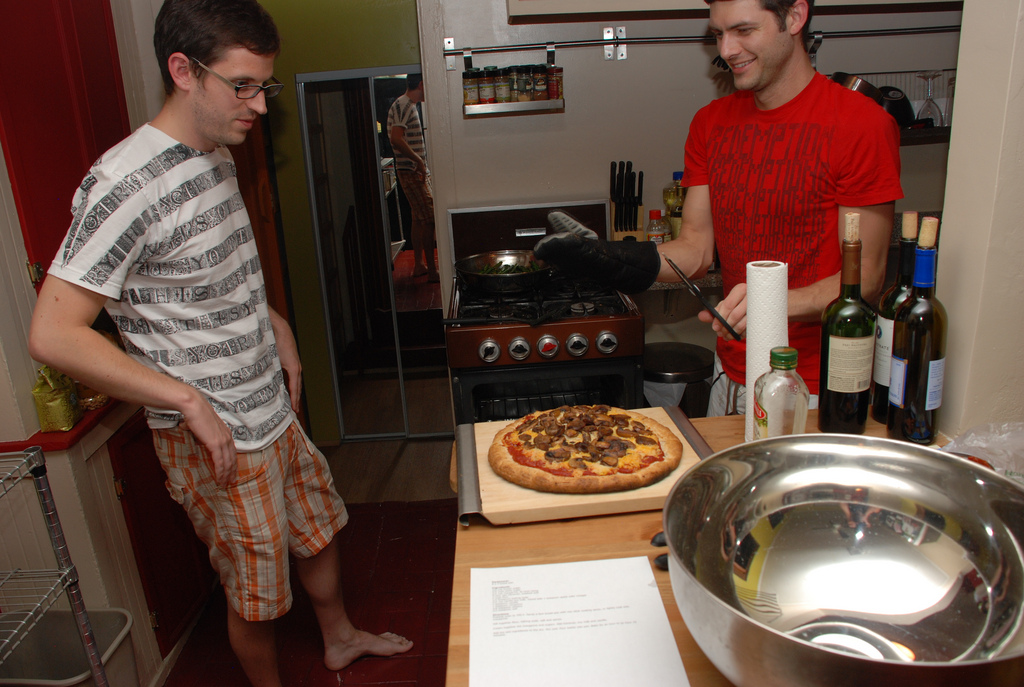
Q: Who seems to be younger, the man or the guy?
A: The man is younger than the guy.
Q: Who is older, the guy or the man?
A: The guy is older than the man.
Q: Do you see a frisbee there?
A: No, there are no frisbees.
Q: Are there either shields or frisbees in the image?
A: No, there are no frisbees or shields.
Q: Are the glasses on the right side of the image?
A: No, the glasses are on the left of the image.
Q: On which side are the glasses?
A: The glasses are on the left of the image.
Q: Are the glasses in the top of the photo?
A: Yes, the glasses are in the top of the image.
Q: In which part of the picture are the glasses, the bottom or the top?
A: The glasses are in the top of the image.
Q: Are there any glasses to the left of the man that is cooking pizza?
A: Yes, there are glasses to the left of the man.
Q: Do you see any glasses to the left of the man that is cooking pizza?
A: Yes, there are glasses to the left of the man.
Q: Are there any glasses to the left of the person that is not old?
A: Yes, there are glasses to the left of the man.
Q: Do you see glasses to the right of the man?
A: No, the glasses are to the left of the man.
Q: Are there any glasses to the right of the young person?
A: No, the glasses are to the left of the man.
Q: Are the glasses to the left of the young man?
A: Yes, the glasses are to the left of the man.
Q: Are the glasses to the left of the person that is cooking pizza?
A: Yes, the glasses are to the left of the man.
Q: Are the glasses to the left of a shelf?
A: No, the glasses are to the left of the man.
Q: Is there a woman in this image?
A: No, there are no women.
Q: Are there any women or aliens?
A: No, there are no women or aliens.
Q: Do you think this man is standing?
A: Yes, the man is standing.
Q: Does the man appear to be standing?
A: Yes, the man is standing.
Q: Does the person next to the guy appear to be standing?
A: Yes, the man is standing.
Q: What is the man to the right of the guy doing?
A: The man is standing.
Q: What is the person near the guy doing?
A: The man is standing.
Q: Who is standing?
A: The man is standing.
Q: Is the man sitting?
A: No, the man is standing.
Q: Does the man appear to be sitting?
A: No, the man is standing.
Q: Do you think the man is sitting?
A: No, the man is standing.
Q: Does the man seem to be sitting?
A: No, the man is standing.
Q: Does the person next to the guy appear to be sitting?
A: No, the man is standing.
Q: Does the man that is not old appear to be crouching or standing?
A: The man is standing.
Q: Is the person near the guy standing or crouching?
A: The man is standing.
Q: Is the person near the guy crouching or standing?
A: The man is standing.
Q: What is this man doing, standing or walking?
A: The man is standing.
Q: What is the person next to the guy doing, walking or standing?
A: The man is standing.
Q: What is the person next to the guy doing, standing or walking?
A: The man is standing.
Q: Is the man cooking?
A: Yes, the man is cooking.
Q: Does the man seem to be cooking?
A: Yes, the man is cooking.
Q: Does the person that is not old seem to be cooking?
A: Yes, the man is cooking.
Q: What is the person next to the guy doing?
A: The man is cooking.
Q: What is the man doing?
A: The man is cooking.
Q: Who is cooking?
A: The man is cooking.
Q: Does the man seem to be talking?
A: No, the man is cooking.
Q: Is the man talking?
A: No, the man is cooking.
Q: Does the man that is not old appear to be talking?
A: No, the man is cooking.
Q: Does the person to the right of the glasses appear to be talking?
A: No, the man is cooking.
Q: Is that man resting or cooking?
A: The man is cooking.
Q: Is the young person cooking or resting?
A: The man is cooking.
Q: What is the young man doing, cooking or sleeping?
A: The man is cooking.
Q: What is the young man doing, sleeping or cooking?
A: The man is cooking.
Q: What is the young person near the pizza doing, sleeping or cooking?
A: The man is cooking.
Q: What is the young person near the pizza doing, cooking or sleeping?
A: The man is cooking.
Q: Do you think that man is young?
A: Yes, the man is young.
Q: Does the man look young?
A: Yes, the man is young.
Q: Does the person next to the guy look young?
A: Yes, the man is young.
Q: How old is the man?
A: The man is young.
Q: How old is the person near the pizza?
A: The man is young.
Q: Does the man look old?
A: No, the man is young.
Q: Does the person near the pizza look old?
A: No, the man is young.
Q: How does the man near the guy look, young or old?
A: The man is young.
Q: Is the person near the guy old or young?
A: The man is young.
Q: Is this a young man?
A: Yes, this is a young man.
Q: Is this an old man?
A: No, this is a young man.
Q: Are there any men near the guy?
A: Yes, there is a man near the guy.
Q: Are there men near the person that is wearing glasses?
A: Yes, there is a man near the guy.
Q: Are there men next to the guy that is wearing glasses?
A: Yes, there is a man next to the guy.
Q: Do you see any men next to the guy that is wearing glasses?
A: Yes, there is a man next to the guy.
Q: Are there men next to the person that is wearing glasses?
A: Yes, there is a man next to the guy.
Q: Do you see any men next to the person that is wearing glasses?
A: Yes, there is a man next to the guy.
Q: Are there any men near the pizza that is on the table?
A: Yes, there is a man near the pizza.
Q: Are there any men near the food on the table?
A: Yes, there is a man near the pizza.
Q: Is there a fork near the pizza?
A: No, there is a man near the pizza.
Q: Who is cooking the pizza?
A: The man is cooking the pizza.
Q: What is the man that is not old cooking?
A: The man is cooking pizza.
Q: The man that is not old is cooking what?
A: The man is cooking pizza.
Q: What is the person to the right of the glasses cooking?
A: The man is cooking pizza.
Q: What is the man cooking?
A: The man is cooking pizza.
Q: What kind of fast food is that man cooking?
A: The man is cooking pizza.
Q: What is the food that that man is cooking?
A: The food is a pizza.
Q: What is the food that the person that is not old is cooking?
A: The food is a pizza.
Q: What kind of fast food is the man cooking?
A: The man is cooking pizza.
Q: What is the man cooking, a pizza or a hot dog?
A: The man is cooking a pizza.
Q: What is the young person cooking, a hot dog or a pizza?
A: The man is cooking a pizza.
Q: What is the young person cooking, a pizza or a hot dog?
A: The man is cooking a pizza.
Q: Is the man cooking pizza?
A: Yes, the man is cooking pizza.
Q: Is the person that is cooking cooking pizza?
A: Yes, the man is cooking pizza.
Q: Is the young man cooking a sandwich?
A: No, the man is cooking pizza.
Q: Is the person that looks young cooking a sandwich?
A: No, the man is cooking pizza.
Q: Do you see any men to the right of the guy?
A: Yes, there is a man to the right of the guy.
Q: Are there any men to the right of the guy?
A: Yes, there is a man to the right of the guy.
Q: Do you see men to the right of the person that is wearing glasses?
A: Yes, there is a man to the right of the guy.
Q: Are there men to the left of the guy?
A: No, the man is to the right of the guy.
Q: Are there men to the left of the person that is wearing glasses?
A: No, the man is to the right of the guy.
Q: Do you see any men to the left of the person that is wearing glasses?
A: No, the man is to the right of the guy.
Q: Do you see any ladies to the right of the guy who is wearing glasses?
A: No, there is a man to the right of the guy.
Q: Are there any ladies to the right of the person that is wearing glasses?
A: No, there is a man to the right of the guy.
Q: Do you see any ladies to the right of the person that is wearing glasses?
A: No, there is a man to the right of the guy.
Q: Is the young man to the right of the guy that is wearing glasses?
A: Yes, the man is to the right of the guy.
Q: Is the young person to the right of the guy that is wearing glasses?
A: Yes, the man is to the right of the guy.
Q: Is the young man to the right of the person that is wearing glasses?
A: Yes, the man is to the right of the guy.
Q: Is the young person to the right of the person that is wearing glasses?
A: Yes, the man is to the right of the guy.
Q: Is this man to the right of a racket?
A: No, the man is to the right of the guy.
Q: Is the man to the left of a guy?
A: No, the man is to the right of a guy.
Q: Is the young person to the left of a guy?
A: No, the man is to the right of a guy.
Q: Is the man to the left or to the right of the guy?
A: The man is to the right of the guy.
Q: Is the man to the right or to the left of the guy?
A: The man is to the right of the guy.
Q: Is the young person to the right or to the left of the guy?
A: The man is to the right of the guy.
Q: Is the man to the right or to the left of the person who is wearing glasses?
A: The man is to the right of the guy.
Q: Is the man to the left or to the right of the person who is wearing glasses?
A: The man is to the right of the guy.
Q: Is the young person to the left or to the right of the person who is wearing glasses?
A: The man is to the right of the guy.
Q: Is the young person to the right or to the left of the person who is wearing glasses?
A: The man is to the right of the guy.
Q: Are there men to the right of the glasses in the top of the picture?
A: Yes, there is a man to the right of the glasses.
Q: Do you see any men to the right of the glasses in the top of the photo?
A: Yes, there is a man to the right of the glasses.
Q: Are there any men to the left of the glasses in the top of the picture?
A: No, the man is to the right of the glasses.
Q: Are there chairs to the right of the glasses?
A: No, there is a man to the right of the glasses.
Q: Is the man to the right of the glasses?
A: Yes, the man is to the right of the glasses.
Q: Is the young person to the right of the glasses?
A: Yes, the man is to the right of the glasses.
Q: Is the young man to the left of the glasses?
A: No, the man is to the right of the glasses.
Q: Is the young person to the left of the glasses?
A: No, the man is to the right of the glasses.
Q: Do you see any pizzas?
A: Yes, there is a pizza.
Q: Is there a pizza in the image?
A: Yes, there is a pizza.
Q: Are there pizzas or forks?
A: Yes, there is a pizza.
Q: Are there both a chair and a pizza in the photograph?
A: No, there is a pizza but no chairs.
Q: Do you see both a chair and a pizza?
A: No, there is a pizza but no chairs.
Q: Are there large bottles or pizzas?
A: Yes, there is a large pizza.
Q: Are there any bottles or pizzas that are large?
A: Yes, the pizza is large.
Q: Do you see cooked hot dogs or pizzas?
A: Yes, there is a cooked pizza.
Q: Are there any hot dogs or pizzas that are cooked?
A: Yes, the pizza is cooked.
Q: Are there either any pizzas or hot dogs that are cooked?
A: Yes, the pizza is cooked.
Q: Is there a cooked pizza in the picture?
A: Yes, there is a cooked pizza.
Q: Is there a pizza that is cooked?
A: Yes, there is a pizza that is cooked.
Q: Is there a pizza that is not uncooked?
A: Yes, there is an cooked pizza.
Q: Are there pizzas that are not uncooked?
A: Yes, there is an cooked pizza.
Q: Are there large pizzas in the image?
A: Yes, there is a large pizza.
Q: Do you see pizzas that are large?
A: Yes, there is a pizza that is large.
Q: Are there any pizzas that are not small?
A: Yes, there is a large pizza.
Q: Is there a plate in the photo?
A: No, there are no plates.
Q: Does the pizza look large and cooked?
A: Yes, the pizza is large and cooked.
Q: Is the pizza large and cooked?
A: Yes, the pizza is large and cooked.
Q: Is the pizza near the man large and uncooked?
A: No, the pizza is large but cooked.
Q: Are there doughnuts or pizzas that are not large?
A: No, there is a pizza but it is large.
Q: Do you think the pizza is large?
A: Yes, the pizza is large.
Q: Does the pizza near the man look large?
A: Yes, the pizza is large.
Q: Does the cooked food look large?
A: Yes, the pizza is large.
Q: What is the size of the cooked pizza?
A: The pizza is large.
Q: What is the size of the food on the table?
A: The pizza is large.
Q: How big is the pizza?
A: The pizza is large.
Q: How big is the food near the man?
A: The pizza is large.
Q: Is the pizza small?
A: No, the pizza is large.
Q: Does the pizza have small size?
A: No, the pizza is large.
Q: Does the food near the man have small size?
A: No, the pizza is large.